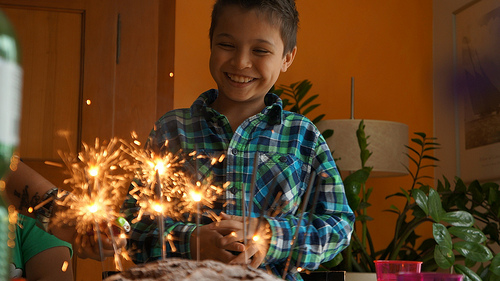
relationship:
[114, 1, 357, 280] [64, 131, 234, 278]
boy smiling at sparklers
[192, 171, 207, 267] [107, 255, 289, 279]
sparkler on top of cake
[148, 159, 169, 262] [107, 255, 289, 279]
sparkler on top of cake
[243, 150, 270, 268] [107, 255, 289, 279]
sparkler on top of cake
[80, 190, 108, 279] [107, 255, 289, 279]
sparkler on top of cake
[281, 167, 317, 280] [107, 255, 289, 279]
sparkler on top of cake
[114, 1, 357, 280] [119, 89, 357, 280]
boy wearing shirt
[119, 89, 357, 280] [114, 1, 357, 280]
shirt on boy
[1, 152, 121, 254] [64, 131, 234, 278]
arm handling sparklers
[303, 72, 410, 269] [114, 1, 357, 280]
lamp behind boy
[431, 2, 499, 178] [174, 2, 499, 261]
artwork hanging on wall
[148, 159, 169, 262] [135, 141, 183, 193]
sparkler has glowing lights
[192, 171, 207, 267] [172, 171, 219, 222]
sparkler has glowing lights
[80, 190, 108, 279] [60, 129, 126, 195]
sparkler has glowing lights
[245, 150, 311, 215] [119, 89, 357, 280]
pocket on shirt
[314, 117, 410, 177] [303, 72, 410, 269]
shade on lamp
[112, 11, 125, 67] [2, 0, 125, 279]
hinge on door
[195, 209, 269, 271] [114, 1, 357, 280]
hands are on boy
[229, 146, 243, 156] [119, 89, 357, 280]
button on shirt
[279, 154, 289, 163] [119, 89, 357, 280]
button on shirt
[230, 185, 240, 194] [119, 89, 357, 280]
button on shirt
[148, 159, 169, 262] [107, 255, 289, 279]
sparkler stuck in cake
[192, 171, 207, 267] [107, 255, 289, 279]
sparkler stuck in cake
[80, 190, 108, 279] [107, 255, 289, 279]
sparkler stuck in cake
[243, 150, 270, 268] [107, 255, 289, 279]
sparkler stuck in cake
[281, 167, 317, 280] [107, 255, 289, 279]
sparkler stuck in cake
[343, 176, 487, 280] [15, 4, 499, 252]
houseplant in background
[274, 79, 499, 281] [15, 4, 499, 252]
house plant in background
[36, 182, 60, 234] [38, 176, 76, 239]
watch on woman's wrist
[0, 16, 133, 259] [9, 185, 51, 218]
person has tatoo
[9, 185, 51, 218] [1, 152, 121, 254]
tatoo on arm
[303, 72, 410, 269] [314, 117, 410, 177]
lamp has shade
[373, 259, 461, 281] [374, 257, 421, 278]
cup of cup